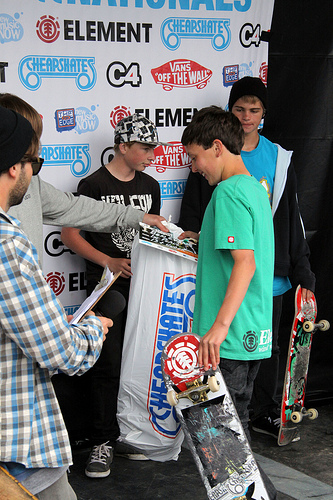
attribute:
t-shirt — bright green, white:
[189, 173, 275, 362]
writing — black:
[239, 326, 274, 353]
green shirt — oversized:
[196, 173, 274, 360]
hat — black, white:
[107, 111, 167, 152]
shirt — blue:
[181, 136, 314, 288]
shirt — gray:
[238, 131, 280, 199]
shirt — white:
[1, 205, 98, 475]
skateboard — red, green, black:
[275, 285, 317, 451]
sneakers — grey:
[83, 440, 118, 481]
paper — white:
[64, 268, 117, 324]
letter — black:
[68, 271, 80, 293]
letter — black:
[53, 22, 161, 52]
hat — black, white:
[113, 111, 172, 154]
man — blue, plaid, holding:
[1, 105, 111, 498]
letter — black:
[151, 106, 165, 128]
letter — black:
[85, 20, 95, 41]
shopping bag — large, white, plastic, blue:
[114, 226, 202, 461]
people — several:
[172, 100, 277, 462]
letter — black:
[115, 20, 126, 41]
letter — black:
[85, 34, 152, 102]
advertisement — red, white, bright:
[149, 58, 213, 91]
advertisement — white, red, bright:
[34, 14, 151, 47]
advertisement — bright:
[159, 13, 232, 51]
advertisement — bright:
[106, 57, 142, 89]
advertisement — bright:
[54, 101, 101, 133]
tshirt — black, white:
[79, 165, 164, 270]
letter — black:
[127, 23, 140, 41]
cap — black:
[224, 73, 272, 112]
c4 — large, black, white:
[102, 59, 145, 89]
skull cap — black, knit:
[206, 80, 275, 103]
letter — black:
[122, 18, 158, 51]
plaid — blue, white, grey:
[9, 236, 40, 333]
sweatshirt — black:
[179, 139, 319, 295]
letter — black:
[62, 13, 74, 40]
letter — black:
[74, 20, 86, 41]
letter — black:
[140, 22, 155, 43]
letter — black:
[116, 19, 126, 42]